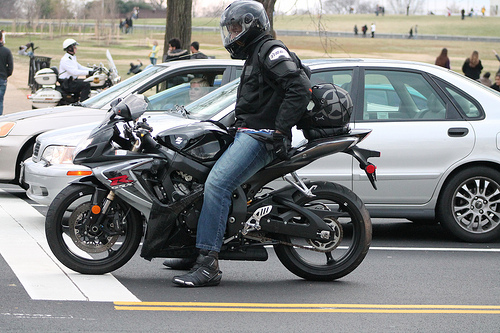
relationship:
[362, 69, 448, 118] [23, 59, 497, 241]
back window on car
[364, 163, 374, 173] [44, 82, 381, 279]
red light on back of bike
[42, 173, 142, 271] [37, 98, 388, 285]
tire on bike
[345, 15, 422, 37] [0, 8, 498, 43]
people in street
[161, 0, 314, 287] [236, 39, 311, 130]
man wearing black jacket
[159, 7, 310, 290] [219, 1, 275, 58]
man wearing a helmet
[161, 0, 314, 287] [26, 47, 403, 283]
man sitting on motorcycle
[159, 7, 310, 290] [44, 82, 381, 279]
man riding bike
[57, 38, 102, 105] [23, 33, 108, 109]
policeman riding a motorcycle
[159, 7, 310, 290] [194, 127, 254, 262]
man wearing a blue jean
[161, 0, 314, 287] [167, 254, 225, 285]
man wearing shoes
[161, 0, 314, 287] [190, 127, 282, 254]
man wearing blue jeans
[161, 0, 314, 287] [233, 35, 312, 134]
man wearing black jacket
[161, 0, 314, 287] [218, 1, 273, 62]
man wearing helmet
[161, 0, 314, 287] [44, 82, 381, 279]
man sitting on bike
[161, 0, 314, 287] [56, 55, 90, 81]
man wearing a shirt.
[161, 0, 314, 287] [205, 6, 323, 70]
man wearing a helmet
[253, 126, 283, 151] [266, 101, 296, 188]
glove on hand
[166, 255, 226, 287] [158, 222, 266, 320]
shoe on foot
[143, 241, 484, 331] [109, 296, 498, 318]
street with yellow lines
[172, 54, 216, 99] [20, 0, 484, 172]
woman in vehicle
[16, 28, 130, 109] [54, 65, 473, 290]
policeman on motorcycle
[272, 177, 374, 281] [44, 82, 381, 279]
tire on bike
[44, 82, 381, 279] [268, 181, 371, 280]
bike with tire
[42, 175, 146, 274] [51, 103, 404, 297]
tire of motorcycle